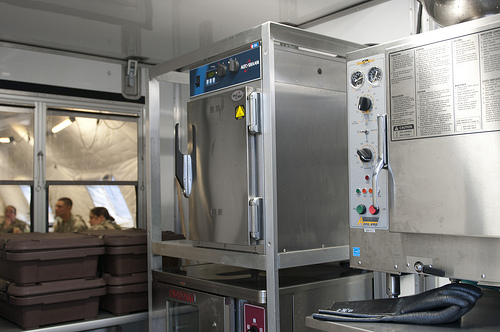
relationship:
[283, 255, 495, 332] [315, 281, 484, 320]
handgloves are plastic handgloves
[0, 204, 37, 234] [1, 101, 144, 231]
soldiers seen through window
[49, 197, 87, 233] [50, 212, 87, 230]
man in uniform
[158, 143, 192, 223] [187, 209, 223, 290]
handle on kitchen equipment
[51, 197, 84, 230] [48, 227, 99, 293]
man sitting on chair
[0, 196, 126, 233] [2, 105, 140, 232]
soldiers in a tent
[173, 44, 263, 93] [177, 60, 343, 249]
label on equipment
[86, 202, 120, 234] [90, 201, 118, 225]
woman with hair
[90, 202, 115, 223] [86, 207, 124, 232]
hair on woman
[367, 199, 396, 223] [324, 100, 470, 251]
button on dishwasher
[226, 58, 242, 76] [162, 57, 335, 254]
button on dishwasher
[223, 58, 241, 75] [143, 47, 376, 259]
button on dishwasher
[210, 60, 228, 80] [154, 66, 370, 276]
knob on dishwasher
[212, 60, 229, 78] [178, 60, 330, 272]
knob on dishwasher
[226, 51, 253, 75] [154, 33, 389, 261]
round dial on dishwasher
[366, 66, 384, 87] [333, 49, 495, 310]
round dial on dishwasher